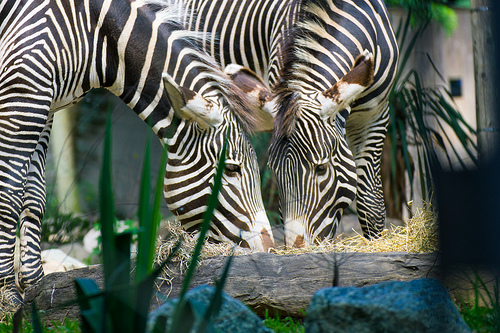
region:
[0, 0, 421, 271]
two zebras eating hay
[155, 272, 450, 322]
two blue rocks on grass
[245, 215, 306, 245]
white noses of zebras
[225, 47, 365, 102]
spotted ears of zebra on right side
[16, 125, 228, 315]
grass growing in front rock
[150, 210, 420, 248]
pile of hay zebras are eating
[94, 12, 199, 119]
black and white stripes on zebra's neck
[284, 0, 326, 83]
black and white mane of zebra on right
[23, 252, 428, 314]
rocks in front of hay pile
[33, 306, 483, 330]
gray surrounding rocks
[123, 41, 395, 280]
the zebras are eating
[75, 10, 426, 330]
black and white zebra's fur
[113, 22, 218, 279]
black and white zebra's fur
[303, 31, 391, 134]
black and white zebra's fur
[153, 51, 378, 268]
two zebras eating hay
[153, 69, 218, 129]
an ear of a zebra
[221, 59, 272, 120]
an ear of a zebra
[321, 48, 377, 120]
an ear of a zebra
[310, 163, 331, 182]
the eye of a zebra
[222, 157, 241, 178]
the eye of a zebra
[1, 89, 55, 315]
the front legs of a zebra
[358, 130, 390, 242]
the front leg of a zebra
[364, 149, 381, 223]
the stripes of a zebra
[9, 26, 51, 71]
the stripes of a zebra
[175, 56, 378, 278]
a couple zebras eating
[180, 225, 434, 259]
hay on the ground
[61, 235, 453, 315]
a gray rock on the ground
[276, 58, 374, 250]
a head of a zebra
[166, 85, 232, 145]
the ear of a zebra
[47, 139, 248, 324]
Tall green grass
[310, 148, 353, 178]
eye of a zebra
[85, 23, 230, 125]
a neck of a zebra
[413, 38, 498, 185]
concrete wall behind zebra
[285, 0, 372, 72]
strips of a zebra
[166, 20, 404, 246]
a couple of zebras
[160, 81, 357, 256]
a couple of zebras eating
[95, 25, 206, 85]
a black and white zebra neck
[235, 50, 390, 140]
a zebras black and white ears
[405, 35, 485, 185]
a concrete wall behind the zebra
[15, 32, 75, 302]
a black and white zebra leg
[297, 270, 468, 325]
a colorful rock in a cage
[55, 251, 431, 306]
a long gray rock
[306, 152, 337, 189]
a black and white zebras eye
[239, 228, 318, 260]
a zebra nose in the hay